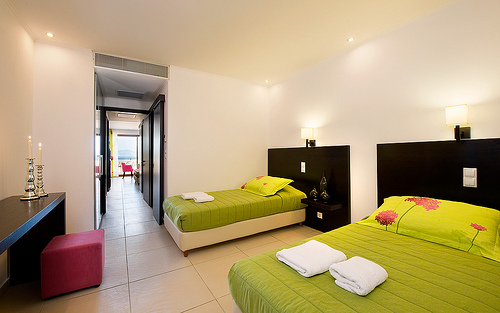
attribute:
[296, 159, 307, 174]
plug — electrical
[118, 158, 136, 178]
chair — pink